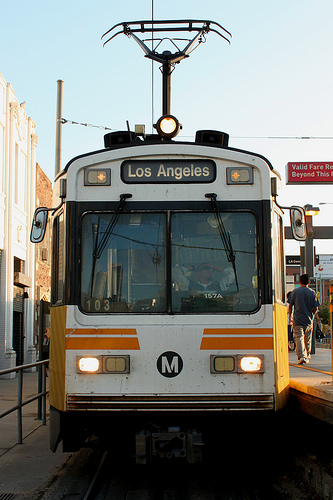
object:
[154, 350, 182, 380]
letter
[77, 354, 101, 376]
headlights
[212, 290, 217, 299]
number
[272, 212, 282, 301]
window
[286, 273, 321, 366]
man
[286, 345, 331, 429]
sidewalk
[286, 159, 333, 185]
sign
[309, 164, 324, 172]
fare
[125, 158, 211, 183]
sign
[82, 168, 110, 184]
light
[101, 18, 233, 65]
conducts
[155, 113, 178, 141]
light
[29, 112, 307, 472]
train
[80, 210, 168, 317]
window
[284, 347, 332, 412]
platform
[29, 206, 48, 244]
mirror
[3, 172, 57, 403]
left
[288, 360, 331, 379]
stripe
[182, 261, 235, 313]
driver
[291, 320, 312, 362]
pants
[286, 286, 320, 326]
shirt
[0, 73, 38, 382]
building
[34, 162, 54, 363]
building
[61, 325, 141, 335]
stripe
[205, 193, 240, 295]
wipers